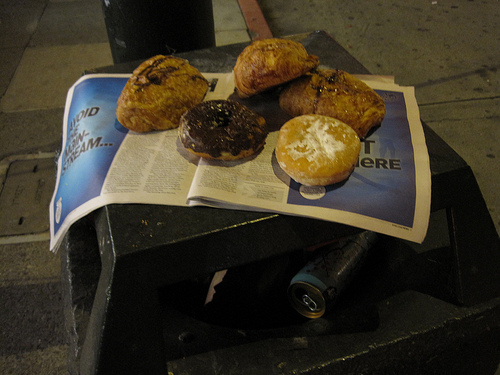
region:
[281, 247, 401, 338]
Can below black stool laying on the cement.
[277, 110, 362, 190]
Doughnut with white powder on it.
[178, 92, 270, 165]
Chocolate covered doughnut next to the doughnut with white powder on it.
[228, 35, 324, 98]
The brown doughnut leaning on the other doughnut.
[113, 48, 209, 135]
Brown doughnut with chocolate syrup on it next to the word Avoid.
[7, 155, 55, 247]
Sewer cover on the ground to the left of the doughnuts on the newspaper.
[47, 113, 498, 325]
Black cement stool the newspaper and doughnuts are placed on.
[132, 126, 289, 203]
White area with black small printed letters on the newspaper.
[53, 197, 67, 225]
White design label on the left blue side of the newspaper near the corner.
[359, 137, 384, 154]
The big printed letter T on the newspaper.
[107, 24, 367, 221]
These are pastries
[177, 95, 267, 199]
This pastry has chocolate frosting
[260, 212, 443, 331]
There is a can under the pastries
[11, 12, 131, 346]
The sidewalk is grey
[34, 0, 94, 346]
The sidewalk is made of concrete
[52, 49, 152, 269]
The paper is grey and blue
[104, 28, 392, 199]
There are 5 pastries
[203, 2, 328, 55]
There is a red stripe on the sidewalk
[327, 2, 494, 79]
The sidewalk has spots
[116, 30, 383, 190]
Pastries over a magazine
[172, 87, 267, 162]
Donut covered with chocolate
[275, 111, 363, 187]
Donut has sugar powder on the center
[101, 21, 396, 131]
Tree danish pastry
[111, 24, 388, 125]
Tree danish pastry covered with chocolate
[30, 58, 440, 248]
Magazine under pastries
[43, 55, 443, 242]
Blue adds on sides of magazine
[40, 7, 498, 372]
Metal trash can in street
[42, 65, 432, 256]
Magazine is over a trash can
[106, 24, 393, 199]
Donuts are over trash can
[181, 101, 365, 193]
Two doughnuts are sitting on a newspaper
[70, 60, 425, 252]
Deserts on a newspaper.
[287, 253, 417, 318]
A can under the stool.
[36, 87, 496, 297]
A newspaper on a black stool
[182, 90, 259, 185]
One of the doughnut has chocolate frosting.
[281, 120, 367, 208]
The doughnut has white powder on it.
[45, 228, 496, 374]
The stool is black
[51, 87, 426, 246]
The newspaper is open to a article.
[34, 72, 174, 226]
the article in the newspaper has black writing.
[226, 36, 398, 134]
The pastry is next to the doughnuts.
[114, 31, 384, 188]
The donuts on the magazine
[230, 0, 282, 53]
Red curb shown above the donuts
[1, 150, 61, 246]
cover for the maintenance box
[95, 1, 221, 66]
Street light pole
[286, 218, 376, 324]
Empty can with blue ring around the top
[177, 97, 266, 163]
Circular donut covered in chocolate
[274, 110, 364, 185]
Circular donut with white on top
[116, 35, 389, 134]
Brown donuts with chocolate drizzle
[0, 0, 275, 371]
The sidewalk to the left of the donuts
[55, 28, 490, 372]
Black object the magazine and donuts are resting on